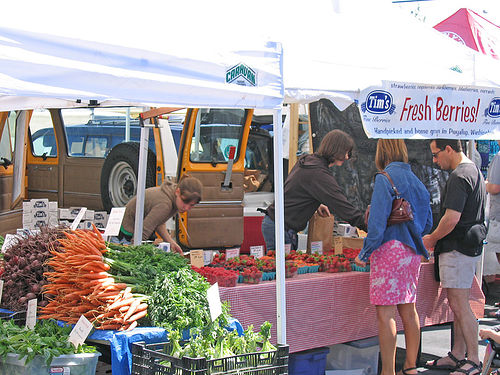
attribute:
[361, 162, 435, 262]
jacket — blue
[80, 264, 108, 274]
carrot — piled, stacked, orange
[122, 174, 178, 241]
hoodie — brown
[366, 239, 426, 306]
skirt — pink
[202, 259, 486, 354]
cloth — red, checkered, pink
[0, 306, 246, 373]
tarp — blue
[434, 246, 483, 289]
shorts — beige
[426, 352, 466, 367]
sandal — black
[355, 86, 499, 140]
sign — white, small, whtie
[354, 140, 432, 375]
woman — buying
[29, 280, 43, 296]
radish — red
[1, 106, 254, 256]
van — yellow, orange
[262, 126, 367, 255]
lady — helping, bending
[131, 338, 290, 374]
cart — full, blue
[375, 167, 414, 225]
purse — brown